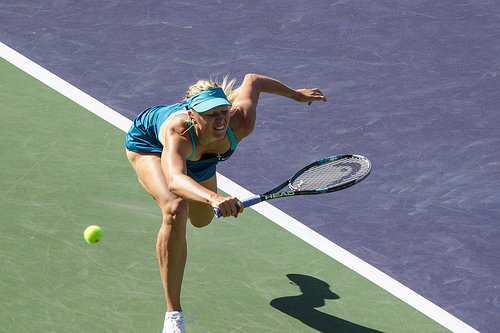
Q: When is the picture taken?
A: Daytime.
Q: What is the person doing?
A: Playing tennis.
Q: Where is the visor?
A: On the head.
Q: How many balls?
A: One.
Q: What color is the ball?
A: Green.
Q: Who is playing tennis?
A: A woman.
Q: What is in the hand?
A: A tennis racket.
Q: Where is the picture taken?
A: Near the stripe of a tennis court, separating the green from the violet.